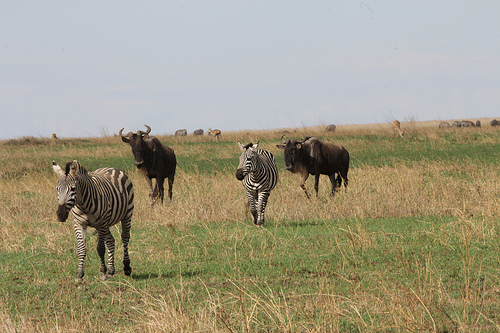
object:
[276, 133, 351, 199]
animal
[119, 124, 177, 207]
animal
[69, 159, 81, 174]
ear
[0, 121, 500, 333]
area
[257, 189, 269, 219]
leg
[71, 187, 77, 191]
eye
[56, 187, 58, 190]
eye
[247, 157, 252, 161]
eye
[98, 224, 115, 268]
leg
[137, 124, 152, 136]
horn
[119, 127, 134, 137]
horn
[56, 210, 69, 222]
mouth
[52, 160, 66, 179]
ear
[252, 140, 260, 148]
ear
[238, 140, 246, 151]
ear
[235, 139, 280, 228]
animal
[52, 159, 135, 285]
animal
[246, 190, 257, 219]
leg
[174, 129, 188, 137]
animal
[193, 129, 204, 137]
animal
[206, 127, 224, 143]
animal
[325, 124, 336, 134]
animal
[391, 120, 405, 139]
animal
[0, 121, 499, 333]
grass